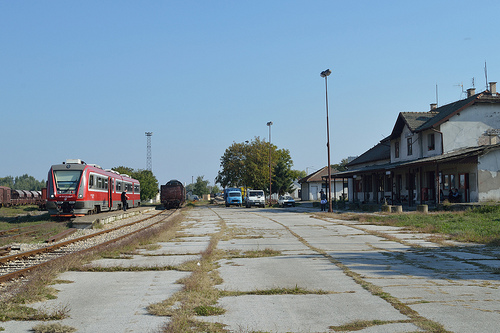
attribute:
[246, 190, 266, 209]
truck — WHITE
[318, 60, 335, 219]
light pole — tall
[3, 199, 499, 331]
grass — BROWN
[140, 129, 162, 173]
pole — power, line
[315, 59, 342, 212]
pole — tall, wooden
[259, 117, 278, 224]
pole — TALL, WOODEN, LIGHT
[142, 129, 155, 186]
pole — metal, electric grid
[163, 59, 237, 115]
sky — gray 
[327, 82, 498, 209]
house — white, worn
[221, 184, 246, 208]
truck — blue, parked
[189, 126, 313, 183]
tree — leafy, green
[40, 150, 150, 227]
train — red, silver